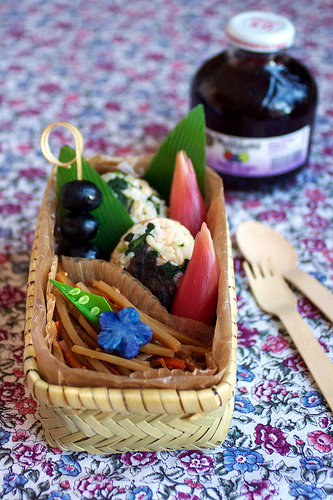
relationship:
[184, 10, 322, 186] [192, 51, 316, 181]
bottle of drink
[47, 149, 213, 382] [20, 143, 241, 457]
wax paper lining of basket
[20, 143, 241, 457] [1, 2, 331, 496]
basket on tablecloth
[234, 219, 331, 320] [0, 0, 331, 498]
spoon on table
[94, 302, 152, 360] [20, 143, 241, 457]
flower in basket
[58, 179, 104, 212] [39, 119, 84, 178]
olive on stick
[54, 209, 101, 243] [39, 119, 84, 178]
olive on stick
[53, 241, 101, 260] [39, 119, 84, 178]
olive on stick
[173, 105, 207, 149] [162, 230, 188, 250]
leaf on rice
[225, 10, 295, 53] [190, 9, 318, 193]
lid on bottle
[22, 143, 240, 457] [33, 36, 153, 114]
basket on table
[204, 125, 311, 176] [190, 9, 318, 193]
label on bottle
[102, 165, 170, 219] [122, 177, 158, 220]
ball with flower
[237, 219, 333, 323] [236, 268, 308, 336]
spoon with fork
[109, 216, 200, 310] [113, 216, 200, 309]
ball with sea weed